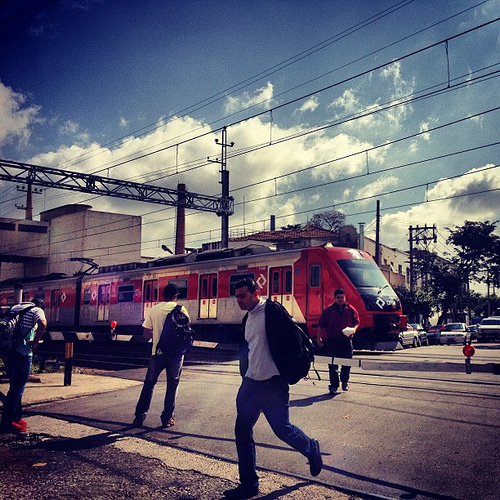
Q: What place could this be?
A: It is a sidewalk.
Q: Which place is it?
A: It is a sidewalk.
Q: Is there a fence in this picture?
A: No, there are no fences.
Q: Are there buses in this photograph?
A: No, there are no buses.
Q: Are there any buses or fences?
A: No, there are no buses or fences.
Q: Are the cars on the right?
A: Yes, the cars are on the right of the image.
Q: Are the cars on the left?
A: No, the cars are on the right of the image.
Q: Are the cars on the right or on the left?
A: The cars are on the right of the image.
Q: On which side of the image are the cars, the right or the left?
A: The cars are on the right of the image.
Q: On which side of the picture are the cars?
A: The cars are on the right of the image.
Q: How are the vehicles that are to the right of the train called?
A: The vehicles are cars.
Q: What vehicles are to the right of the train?
A: The vehicles are cars.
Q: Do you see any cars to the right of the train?
A: Yes, there are cars to the right of the train.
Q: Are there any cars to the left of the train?
A: No, the cars are to the right of the train.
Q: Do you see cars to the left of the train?
A: No, the cars are to the right of the train.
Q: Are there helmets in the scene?
A: No, there are no helmets.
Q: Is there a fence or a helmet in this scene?
A: No, there are no helmets or fences.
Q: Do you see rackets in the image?
A: No, there are no rackets.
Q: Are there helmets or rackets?
A: No, there are no rackets or helmets.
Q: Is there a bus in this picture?
A: No, there are no buses.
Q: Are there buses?
A: No, there are no buses.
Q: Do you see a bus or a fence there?
A: No, there are no buses or fences.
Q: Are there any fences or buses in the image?
A: No, there are no buses or fences.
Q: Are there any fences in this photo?
A: No, there are no fences.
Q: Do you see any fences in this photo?
A: No, there are no fences.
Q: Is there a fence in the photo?
A: No, there are no fences.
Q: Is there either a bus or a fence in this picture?
A: No, there are no fences or buses.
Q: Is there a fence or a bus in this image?
A: No, there are no fences or buses.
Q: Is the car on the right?
A: Yes, the car is on the right of the image.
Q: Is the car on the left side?
A: No, the car is on the right of the image.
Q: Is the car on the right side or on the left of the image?
A: The car is on the right of the image.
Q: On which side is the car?
A: The car is on the right of the image.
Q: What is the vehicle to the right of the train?
A: The vehicle is a car.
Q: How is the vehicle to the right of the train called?
A: The vehicle is a car.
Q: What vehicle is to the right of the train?
A: The vehicle is a car.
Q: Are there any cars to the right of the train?
A: Yes, there is a car to the right of the train.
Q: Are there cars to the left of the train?
A: No, the car is to the right of the train.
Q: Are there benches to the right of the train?
A: No, there is a car to the right of the train.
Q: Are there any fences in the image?
A: No, there are no fences.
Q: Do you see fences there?
A: No, there are no fences.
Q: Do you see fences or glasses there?
A: No, there are no fences or glasses.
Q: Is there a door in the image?
A: Yes, there is a door.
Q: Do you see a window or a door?
A: Yes, there is a door.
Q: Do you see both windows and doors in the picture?
A: Yes, there are both a door and windows.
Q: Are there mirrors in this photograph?
A: No, there are no mirrors.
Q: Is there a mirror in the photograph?
A: No, there are no mirrors.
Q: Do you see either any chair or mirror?
A: No, there are no mirrors or chairs.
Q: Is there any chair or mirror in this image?
A: No, there are no mirrors or chairs.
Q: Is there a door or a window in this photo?
A: Yes, there is a door.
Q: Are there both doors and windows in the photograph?
A: Yes, there are both a door and windows.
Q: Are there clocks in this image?
A: No, there are no clocks.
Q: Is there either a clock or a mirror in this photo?
A: No, there are no clocks or mirrors.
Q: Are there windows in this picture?
A: Yes, there is a window.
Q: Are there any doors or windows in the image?
A: Yes, there is a window.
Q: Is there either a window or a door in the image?
A: Yes, there is a window.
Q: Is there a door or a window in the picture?
A: Yes, there is a window.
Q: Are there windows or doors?
A: Yes, there is a window.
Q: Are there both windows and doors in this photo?
A: Yes, there are both a window and doors.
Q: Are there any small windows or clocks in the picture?
A: Yes, there is a small window.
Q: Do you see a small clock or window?
A: Yes, there is a small window.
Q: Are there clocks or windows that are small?
A: Yes, the window is small.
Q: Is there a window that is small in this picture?
A: Yes, there is a small window.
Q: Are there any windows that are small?
A: Yes, there is a window that is small.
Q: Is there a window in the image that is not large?
A: Yes, there is a small window.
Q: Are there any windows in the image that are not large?
A: Yes, there is a small window.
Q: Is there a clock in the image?
A: No, there are no clocks.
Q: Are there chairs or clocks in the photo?
A: No, there are no clocks or chairs.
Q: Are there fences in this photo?
A: No, there are no fences.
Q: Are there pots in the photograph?
A: No, there are no pots.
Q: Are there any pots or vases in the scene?
A: No, there are no pots or vases.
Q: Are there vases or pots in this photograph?
A: No, there are no pots or vases.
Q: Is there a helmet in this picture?
A: No, there are no helmets.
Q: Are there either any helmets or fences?
A: No, there are no helmets or fences.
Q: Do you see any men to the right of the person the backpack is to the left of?
A: Yes, there is a man to the right of the person.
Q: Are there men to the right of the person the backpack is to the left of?
A: Yes, there is a man to the right of the person.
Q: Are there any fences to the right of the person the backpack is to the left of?
A: No, there is a man to the right of the person.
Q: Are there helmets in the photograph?
A: No, there are no helmets.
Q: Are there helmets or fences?
A: No, there are no helmets or fences.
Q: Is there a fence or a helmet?
A: No, there are no helmets or fences.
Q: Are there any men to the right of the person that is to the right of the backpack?
A: Yes, there is a man to the right of the person.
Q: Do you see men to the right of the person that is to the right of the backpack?
A: Yes, there is a man to the right of the person.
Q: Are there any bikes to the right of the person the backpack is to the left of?
A: No, there is a man to the right of the person.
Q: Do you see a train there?
A: Yes, there is a train.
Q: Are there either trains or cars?
A: Yes, there is a train.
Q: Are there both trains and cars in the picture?
A: Yes, there are both a train and a car.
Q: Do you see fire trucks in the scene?
A: No, there are no fire trucks.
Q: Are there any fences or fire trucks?
A: No, there are no fire trucks or fences.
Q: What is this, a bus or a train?
A: This is a train.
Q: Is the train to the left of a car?
A: Yes, the train is to the left of a car.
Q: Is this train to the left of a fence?
A: No, the train is to the left of a car.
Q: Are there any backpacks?
A: Yes, there is a backpack.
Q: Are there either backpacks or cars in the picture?
A: Yes, there is a backpack.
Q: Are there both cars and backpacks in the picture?
A: Yes, there are both a backpack and a car.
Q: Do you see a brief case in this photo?
A: No, there are no briefcases.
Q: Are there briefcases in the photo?
A: No, there are no briefcases.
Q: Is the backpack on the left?
A: Yes, the backpack is on the left of the image.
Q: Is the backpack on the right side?
A: No, the backpack is on the left of the image.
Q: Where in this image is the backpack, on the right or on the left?
A: The backpack is on the left of the image.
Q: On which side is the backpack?
A: The backpack is on the left of the image.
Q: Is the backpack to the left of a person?
A: Yes, the backpack is to the left of a person.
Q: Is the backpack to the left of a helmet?
A: No, the backpack is to the left of a person.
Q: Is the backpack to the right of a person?
A: No, the backpack is to the left of a person.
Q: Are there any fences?
A: No, there are no fences.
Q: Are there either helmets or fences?
A: No, there are no fences or helmets.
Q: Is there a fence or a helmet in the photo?
A: No, there are no fences or helmets.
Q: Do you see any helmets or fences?
A: No, there are no fences or helmets.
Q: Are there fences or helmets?
A: No, there are no fences or helmets.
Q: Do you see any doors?
A: Yes, there is a door.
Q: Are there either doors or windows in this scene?
A: Yes, there is a door.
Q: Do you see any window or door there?
A: Yes, there is a door.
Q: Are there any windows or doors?
A: Yes, there is a door.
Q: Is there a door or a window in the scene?
A: Yes, there is a door.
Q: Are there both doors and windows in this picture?
A: Yes, there are both a door and a window.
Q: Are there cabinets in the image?
A: No, there are no cabinets.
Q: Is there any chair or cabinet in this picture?
A: No, there are no cabinets or chairs.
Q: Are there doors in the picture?
A: Yes, there is a door.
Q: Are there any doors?
A: Yes, there is a door.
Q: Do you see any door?
A: Yes, there is a door.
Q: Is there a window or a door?
A: Yes, there is a door.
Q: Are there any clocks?
A: No, there are no clocks.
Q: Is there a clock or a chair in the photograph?
A: No, there are no clocks or chairs.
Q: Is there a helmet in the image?
A: No, there are no helmets.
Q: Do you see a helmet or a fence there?
A: No, there are no helmets or fences.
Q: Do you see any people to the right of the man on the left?
A: Yes, there is a person to the right of the man.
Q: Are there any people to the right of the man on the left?
A: Yes, there is a person to the right of the man.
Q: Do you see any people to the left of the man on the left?
A: No, the person is to the right of the man.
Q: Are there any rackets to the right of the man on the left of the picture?
A: No, there is a person to the right of the man.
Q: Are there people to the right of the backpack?
A: Yes, there is a person to the right of the backpack.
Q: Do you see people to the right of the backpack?
A: Yes, there is a person to the right of the backpack.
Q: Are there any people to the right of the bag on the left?
A: Yes, there is a person to the right of the backpack.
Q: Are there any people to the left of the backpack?
A: No, the person is to the right of the backpack.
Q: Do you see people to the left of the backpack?
A: No, the person is to the right of the backpack.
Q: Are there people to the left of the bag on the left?
A: No, the person is to the right of the backpack.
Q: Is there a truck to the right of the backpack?
A: No, there is a person to the right of the backpack.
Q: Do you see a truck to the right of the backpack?
A: No, there is a person to the right of the backpack.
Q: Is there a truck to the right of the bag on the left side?
A: No, there is a person to the right of the backpack.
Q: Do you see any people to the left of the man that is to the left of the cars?
A: Yes, there is a person to the left of the man.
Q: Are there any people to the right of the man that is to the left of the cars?
A: No, the person is to the left of the man.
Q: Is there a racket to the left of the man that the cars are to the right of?
A: No, there is a person to the left of the man.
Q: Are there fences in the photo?
A: No, there are no fences.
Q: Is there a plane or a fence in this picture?
A: No, there are no fences or airplanes.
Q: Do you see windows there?
A: Yes, there is a window.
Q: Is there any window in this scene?
A: Yes, there is a window.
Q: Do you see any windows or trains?
A: Yes, there is a window.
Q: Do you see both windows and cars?
A: Yes, there are both a window and a car.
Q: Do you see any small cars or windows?
A: Yes, there is a small window.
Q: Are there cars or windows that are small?
A: Yes, the window is small.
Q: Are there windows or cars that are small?
A: Yes, the window is small.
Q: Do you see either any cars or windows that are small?
A: Yes, the window is small.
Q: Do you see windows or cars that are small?
A: Yes, the window is small.